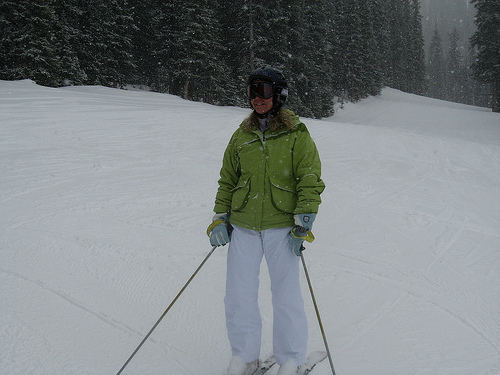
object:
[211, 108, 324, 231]
coat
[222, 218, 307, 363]
pants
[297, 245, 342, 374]
ski pole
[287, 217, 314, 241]
hand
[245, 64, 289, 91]
helmet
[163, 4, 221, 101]
trees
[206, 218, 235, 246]
glove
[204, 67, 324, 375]
person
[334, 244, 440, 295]
tracks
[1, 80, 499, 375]
snow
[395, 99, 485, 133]
slope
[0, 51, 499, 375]
mountain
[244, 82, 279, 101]
mask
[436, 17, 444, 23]
protection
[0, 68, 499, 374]
ground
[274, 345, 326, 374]
skis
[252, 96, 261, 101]
nose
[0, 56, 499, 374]
hill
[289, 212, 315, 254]
gloves